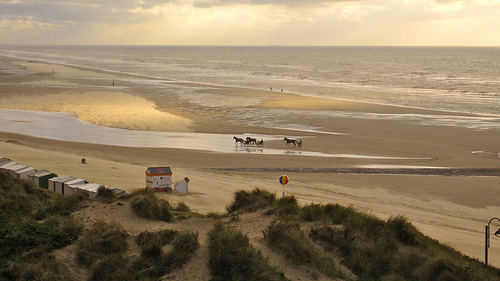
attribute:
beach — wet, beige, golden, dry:
[0, 61, 498, 268]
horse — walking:
[284, 138, 299, 148]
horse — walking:
[247, 137, 259, 145]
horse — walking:
[233, 135, 244, 145]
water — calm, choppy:
[0, 42, 499, 114]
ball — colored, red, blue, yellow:
[279, 176, 290, 186]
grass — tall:
[4, 178, 499, 280]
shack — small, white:
[145, 166, 172, 192]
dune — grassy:
[230, 209, 270, 238]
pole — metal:
[482, 225, 492, 267]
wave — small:
[430, 70, 481, 86]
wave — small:
[270, 62, 302, 71]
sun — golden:
[18, 91, 172, 130]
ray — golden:
[271, 95, 360, 110]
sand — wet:
[213, 144, 285, 160]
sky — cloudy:
[0, 0, 498, 47]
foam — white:
[430, 72, 497, 84]